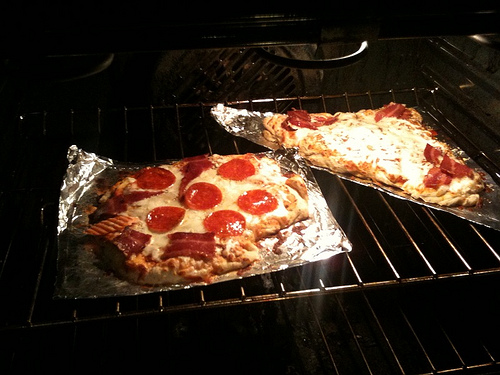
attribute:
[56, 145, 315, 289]
pizza — round, lopsided, not slices, individual pizza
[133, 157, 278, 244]
pepperoni — sliced, crispy, seven slices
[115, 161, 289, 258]
cheese — mozzarella, melted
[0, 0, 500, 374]
oven — not freezer, black, dark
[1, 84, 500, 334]
rack — silver metal, top rack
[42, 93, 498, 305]
tinfoil — aluminum foil, crinkly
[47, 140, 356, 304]
tinfoil — aluminum foil, crinkly, folded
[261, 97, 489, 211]
pizza — triangular, snubbed triangle, not slices, individual pizza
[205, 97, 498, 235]
tinfoil — aluminum foil, crinkly, folded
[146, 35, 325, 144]
fan — circular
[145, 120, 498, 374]
lower rack — silver metal too, silver metal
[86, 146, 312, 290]
crust — lumpy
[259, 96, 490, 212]
crust — lumpy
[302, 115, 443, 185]
cheese — maybe atop meat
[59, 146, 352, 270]
reflected light — glare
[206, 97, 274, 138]
reflected light — glare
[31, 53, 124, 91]
heating coil — hose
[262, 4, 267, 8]
freezer — invisible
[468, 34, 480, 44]
light source — invisible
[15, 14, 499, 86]
heating coils — three, hard to see, heating element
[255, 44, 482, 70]
oven light — on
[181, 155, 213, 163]
pepperoni slice — under cheese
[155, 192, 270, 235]
grease — shiny